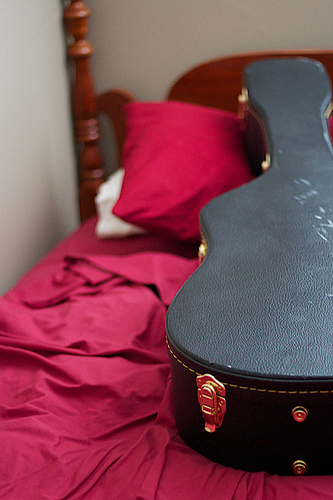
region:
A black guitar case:
[188, 68, 332, 478]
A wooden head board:
[65, 12, 332, 225]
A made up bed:
[4, 222, 331, 499]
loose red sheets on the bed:
[2, 264, 328, 497]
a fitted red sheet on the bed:
[28, 218, 168, 291]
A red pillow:
[114, 101, 259, 238]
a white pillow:
[97, 170, 160, 240]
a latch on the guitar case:
[190, 377, 244, 436]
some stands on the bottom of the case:
[288, 400, 311, 477]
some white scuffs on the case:
[281, 168, 331, 249]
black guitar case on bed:
[46, 19, 308, 497]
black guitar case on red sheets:
[26, 40, 331, 451]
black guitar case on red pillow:
[70, 44, 331, 420]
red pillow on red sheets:
[62, 80, 190, 367]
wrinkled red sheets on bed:
[0, 245, 168, 439]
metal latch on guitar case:
[171, 371, 232, 449]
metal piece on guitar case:
[294, 402, 307, 424]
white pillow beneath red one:
[33, 156, 153, 261]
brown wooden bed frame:
[19, 14, 280, 280]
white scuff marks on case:
[293, 166, 332, 277]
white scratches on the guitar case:
[290, 174, 332, 243]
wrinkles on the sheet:
[84, 462, 108, 484]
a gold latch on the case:
[193, 374, 238, 434]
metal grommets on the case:
[287, 400, 312, 484]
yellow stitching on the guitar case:
[234, 381, 324, 399]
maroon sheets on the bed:
[49, 263, 143, 445]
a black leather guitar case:
[223, 213, 278, 338]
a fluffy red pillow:
[136, 100, 226, 196]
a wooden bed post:
[69, 9, 106, 191]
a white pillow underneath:
[97, 186, 116, 236]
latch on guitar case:
[185, 367, 240, 440]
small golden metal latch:
[192, 373, 230, 432]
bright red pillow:
[110, 99, 261, 239]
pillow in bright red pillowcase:
[110, 95, 255, 241]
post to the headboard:
[57, 3, 112, 251]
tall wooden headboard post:
[57, 0, 118, 231]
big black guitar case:
[164, 55, 330, 477]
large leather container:
[163, 56, 331, 480]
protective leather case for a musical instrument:
[167, 53, 332, 474]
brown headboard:
[63, 0, 332, 231]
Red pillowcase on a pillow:
[126, 97, 242, 229]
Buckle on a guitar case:
[197, 369, 228, 437]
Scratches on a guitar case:
[287, 157, 331, 284]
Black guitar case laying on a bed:
[243, 65, 324, 482]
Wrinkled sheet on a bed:
[60, 239, 153, 412]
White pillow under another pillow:
[97, 173, 113, 238]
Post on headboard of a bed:
[74, 12, 97, 220]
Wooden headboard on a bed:
[98, 43, 332, 76]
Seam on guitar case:
[228, 382, 328, 401]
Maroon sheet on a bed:
[45, 296, 161, 445]